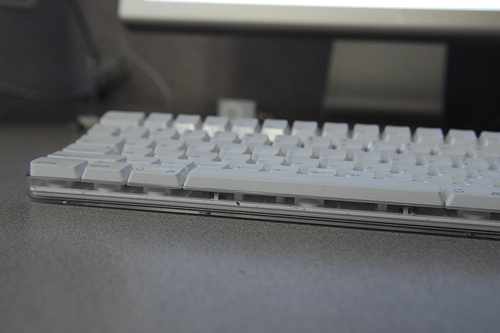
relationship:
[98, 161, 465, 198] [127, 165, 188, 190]
bottom row of button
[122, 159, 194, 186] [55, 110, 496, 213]
button on keyboard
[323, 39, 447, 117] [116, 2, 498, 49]
stand on monitor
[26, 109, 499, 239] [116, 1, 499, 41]
keyboard under monitor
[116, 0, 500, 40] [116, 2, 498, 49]
bottom edge on monitor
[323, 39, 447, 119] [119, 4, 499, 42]
stand on computer screen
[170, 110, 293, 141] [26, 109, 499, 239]
light on keyboard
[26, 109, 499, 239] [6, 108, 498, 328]
keyboard on top of table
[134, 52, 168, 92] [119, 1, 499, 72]
wires behind computer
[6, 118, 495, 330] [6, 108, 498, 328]
surface of table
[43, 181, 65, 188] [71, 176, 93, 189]
pad between space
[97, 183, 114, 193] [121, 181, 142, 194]
pad between space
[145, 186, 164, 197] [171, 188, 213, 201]
pad between space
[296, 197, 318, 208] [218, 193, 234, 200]
pad between space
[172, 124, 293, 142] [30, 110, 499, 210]
light reflecting off sides of keys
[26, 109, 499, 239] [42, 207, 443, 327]
keyboard on desk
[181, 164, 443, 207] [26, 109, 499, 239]
space bar on keyboard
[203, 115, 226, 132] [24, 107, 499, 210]
key of keyboard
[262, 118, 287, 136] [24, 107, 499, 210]
key of keyboard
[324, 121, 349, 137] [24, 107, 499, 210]
key of keyboard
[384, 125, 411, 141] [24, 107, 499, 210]
key of keyboard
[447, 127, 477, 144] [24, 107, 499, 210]
key of keyboard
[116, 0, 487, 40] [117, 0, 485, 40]
bottom edge of computer screen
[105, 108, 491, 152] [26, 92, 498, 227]
keys on keyboard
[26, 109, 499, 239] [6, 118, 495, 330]
keyboard seen from surface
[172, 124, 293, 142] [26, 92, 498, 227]
light shining down on keyboard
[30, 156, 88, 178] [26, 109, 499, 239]
key on keyboard